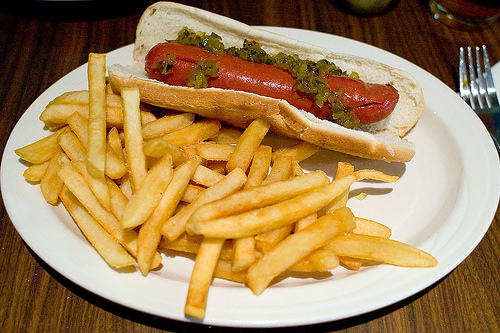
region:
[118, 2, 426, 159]
A hot dog in a bun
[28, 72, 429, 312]
A side of golden, shoestring fries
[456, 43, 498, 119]
The head of a four-pronged fork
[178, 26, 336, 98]
Green relish on a hot dog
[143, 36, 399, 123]
A hot dog in a bun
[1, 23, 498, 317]
A white plate of food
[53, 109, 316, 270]
Crispy, golden fries beside a hot dog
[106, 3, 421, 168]
A bun holding a hot dog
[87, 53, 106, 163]
A shoestring fry laying down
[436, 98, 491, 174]
Edge of a white plate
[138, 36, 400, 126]
hot dog is in the bun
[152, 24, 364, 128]
green relish on top of hot dog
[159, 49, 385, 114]
light reflecting on hot dog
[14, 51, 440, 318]
fries next to hot dog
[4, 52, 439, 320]
the fries are yellow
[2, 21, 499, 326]
the plate is round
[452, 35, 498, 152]
fork next to plate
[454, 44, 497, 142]
light reflecting on fork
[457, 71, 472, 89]
brown stain on fork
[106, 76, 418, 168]
the bread is brown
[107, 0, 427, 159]
The hotdog is on a bun.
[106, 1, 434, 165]
The hotdog is cooked.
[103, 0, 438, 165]
The hotdog has relish on it.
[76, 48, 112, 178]
The french fry is cooked.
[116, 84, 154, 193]
The french fry is cooked.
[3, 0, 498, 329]
The plate is full.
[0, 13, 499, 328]
The plate is white.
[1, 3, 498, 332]
The plate is round.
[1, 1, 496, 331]
The plate is in use.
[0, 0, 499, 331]
A fork is lying next to the plate.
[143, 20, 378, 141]
a hotdog on a bun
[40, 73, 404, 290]
fries on the plate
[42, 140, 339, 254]
fries on the plate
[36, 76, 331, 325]
a pile of french fries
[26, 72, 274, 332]
a white plate with french fries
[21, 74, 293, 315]
french fries on a white plate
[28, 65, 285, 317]
french fries on a plate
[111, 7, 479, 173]
a hotdog in a bun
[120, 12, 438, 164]
a hotdog with relish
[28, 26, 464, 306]
a white plate with food on it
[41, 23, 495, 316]
a white plate on a table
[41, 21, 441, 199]
a white plate with a hotdog on it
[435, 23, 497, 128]
a silver fork